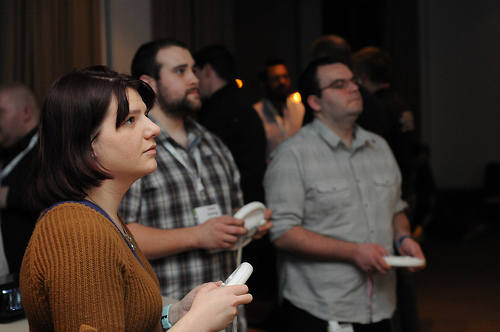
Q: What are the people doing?
A: Playing game.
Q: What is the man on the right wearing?
A: A button down shirt.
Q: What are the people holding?
A: Wii controllers.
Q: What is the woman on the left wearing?
A: A brown sweater.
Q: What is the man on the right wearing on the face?
A: Glasses.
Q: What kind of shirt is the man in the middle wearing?
A: A checkered shirt.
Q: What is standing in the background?
A: People are standing in the background.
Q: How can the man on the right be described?
A: A middle aged man standing with a game controller.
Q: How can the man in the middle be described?
A: A young man wearing a plaid shirt holding a game controller.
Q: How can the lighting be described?
A: Dark.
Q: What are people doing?
A: Playing a game.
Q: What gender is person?
A: Female.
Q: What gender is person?
A: Male.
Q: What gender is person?
A: Male.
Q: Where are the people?
A: Inside a room.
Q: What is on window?
A: Curtains.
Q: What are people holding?
A: Controllers.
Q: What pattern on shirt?
A: Plaid.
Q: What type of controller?
A: Wii.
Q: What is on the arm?
A: Rolled up sleeve.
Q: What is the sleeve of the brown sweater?
A: Ribbed.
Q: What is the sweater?
A: Brown.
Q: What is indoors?
A: The guys.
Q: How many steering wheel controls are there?
A: 1.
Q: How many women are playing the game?
A: 1.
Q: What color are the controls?
A: White.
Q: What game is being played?
A: Nintendo Wii.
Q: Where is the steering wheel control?
A: In the middle player's hand.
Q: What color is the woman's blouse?
A: Brown.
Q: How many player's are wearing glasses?
A: 1.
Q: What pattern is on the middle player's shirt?
A: Plaid.